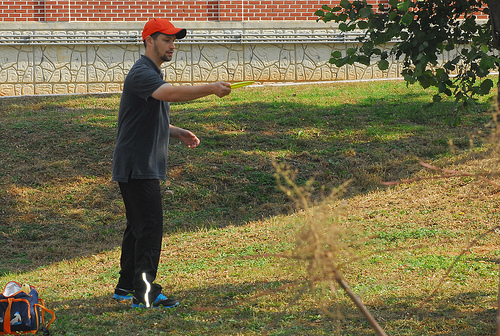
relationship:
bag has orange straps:
[2, 280, 38, 334] [35, 293, 57, 333]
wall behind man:
[16, 8, 101, 67] [109, 9, 224, 309]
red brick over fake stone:
[1, 0, 489, 20] [0, 29, 499, 96]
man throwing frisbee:
[111, 16, 257, 311] [217, 68, 266, 99]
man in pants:
[111, 16, 257, 311] [108, 173, 178, 290]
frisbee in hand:
[228, 78, 254, 89] [213, 78, 230, 99]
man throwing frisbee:
[111, 16, 257, 311] [228, 77, 258, 87]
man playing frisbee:
[111, 16, 257, 311] [229, 78, 254, 88]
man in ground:
[111, 16, 257, 311] [0, 73, 499, 335]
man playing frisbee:
[111, 16, 257, 311] [226, 78, 255, 88]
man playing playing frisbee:
[111, 16, 257, 311] [109, 16, 296, 261]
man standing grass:
[111, 16, 257, 311] [7, 80, 484, 328]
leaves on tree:
[309, 2, 499, 125] [317, 4, 484, 112]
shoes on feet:
[108, 272, 198, 314] [114, 278, 178, 314]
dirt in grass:
[213, 263, 278, 288] [3, 92, 104, 245]